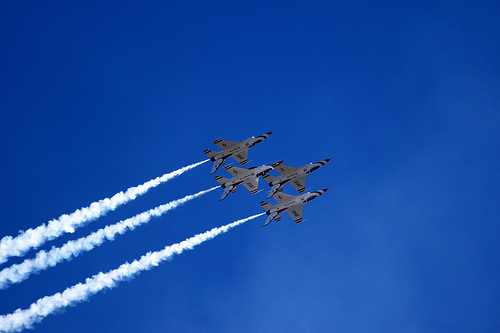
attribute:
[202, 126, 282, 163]
plane — gray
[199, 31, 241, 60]
sky — blue, cloudless, clear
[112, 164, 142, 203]
smoke — white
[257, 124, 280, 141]
nose — black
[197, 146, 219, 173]
tail — black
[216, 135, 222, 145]
wing — black